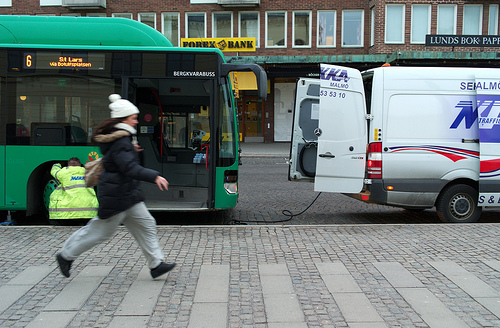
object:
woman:
[81, 106, 170, 264]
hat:
[110, 84, 143, 120]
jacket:
[93, 120, 137, 212]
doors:
[298, 65, 372, 212]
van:
[321, 60, 484, 224]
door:
[161, 78, 215, 189]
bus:
[55, 21, 247, 226]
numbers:
[19, 52, 52, 92]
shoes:
[43, 251, 195, 286]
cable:
[254, 178, 338, 242]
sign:
[182, 23, 283, 65]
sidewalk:
[189, 207, 399, 307]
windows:
[220, 8, 396, 61]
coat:
[50, 162, 120, 223]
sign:
[46, 55, 100, 91]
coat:
[95, 122, 145, 214]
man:
[56, 147, 102, 211]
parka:
[105, 116, 138, 142]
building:
[182, 1, 409, 86]